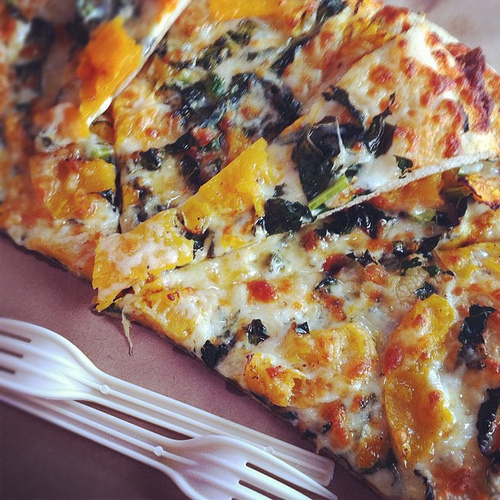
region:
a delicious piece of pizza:
[18, 13, 495, 498]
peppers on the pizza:
[166, 121, 293, 239]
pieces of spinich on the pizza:
[230, 95, 409, 297]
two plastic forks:
[1, 288, 361, 495]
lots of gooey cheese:
[195, 244, 321, 333]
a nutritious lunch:
[154, 59, 497, 328]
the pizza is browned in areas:
[391, 37, 487, 147]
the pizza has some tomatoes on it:
[63, 35, 384, 295]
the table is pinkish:
[16, 278, 172, 408]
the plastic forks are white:
[6, 300, 313, 498]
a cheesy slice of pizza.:
[106, 154, 498, 494]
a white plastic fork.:
[0, 314, 344, 492]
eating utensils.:
[0, 305, 337, 497]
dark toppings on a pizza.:
[195, 303, 297, 360]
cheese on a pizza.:
[379, 349, 439, 463]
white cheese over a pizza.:
[390, 365, 480, 465]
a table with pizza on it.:
[0, 230, 383, 498]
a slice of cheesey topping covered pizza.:
[45, 3, 424, 277]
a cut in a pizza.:
[76, 140, 495, 325]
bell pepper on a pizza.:
[133, 118, 291, 288]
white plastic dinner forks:
[4, 307, 356, 498]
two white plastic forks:
[0, 303, 345, 498]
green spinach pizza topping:
[285, 80, 403, 226]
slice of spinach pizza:
[73, 5, 493, 309]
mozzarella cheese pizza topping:
[148, 275, 309, 388]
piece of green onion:
[299, 171, 360, 226]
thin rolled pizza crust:
[349, 5, 499, 192]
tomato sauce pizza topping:
[240, 275, 283, 312]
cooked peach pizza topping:
[179, 134, 286, 257]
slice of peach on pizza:
[379, 285, 466, 497]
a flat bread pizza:
[5, 9, 499, 345]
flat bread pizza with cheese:
[14, 20, 492, 428]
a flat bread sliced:
[17, 15, 499, 445]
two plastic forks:
[8, 12, 498, 476]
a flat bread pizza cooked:
[9, 0, 496, 459]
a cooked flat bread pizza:
[9, 7, 499, 454]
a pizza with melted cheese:
[5, 9, 475, 405]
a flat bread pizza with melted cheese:
[26, 10, 499, 391]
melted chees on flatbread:
[8, 35, 498, 441]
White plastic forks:
[1, 317, 341, 499]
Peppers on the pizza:
[385, 293, 456, 471]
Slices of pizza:
[0, 1, 497, 498]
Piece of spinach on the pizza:
[263, 198, 313, 230]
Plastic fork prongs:
[2, 326, 35, 400]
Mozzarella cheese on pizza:
[175, 271, 226, 326]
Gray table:
[1, 429, 54, 473]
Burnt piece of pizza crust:
[462, 47, 499, 117]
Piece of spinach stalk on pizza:
[306, 173, 351, 209]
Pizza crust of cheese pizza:
[428, 91, 496, 153]